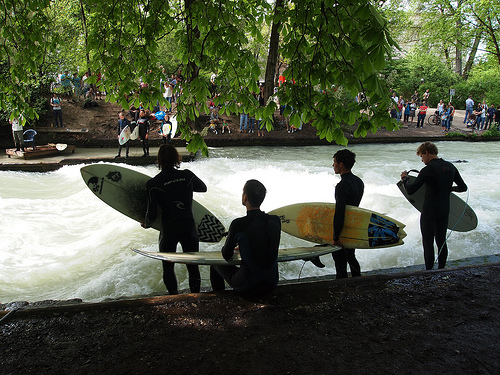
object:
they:
[141, 142, 468, 297]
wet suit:
[209, 209, 282, 294]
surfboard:
[129, 245, 344, 266]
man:
[209, 179, 282, 303]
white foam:
[53, 242, 129, 288]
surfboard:
[265, 202, 407, 250]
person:
[135, 109, 151, 157]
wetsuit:
[135, 116, 151, 158]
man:
[400, 141, 467, 271]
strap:
[407, 169, 420, 175]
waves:
[1, 161, 157, 292]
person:
[463, 95, 474, 124]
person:
[436, 99, 444, 116]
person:
[415, 100, 429, 129]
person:
[422, 89, 431, 105]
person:
[410, 90, 420, 103]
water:
[0, 140, 499, 305]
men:
[113, 111, 134, 159]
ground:
[3, 254, 500, 372]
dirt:
[3, 317, 498, 370]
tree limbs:
[172, 1, 402, 156]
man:
[140, 143, 208, 295]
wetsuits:
[331, 171, 365, 280]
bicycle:
[428, 110, 442, 125]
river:
[0, 140, 500, 304]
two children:
[207, 119, 231, 136]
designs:
[87, 176, 104, 195]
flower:
[368, 215, 400, 249]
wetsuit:
[145, 169, 208, 294]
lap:
[210, 260, 238, 287]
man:
[331, 148, 364, 279]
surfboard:
[80, 164, 226, 243]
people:
[443, 102, 455, 132]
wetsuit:
[402, 158, 468, 271]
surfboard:
[396, 174, 479, 233]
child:
[209, 120, 219, 135]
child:
[221, 119, 231, 133]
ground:
[1, 88, 500, 146]